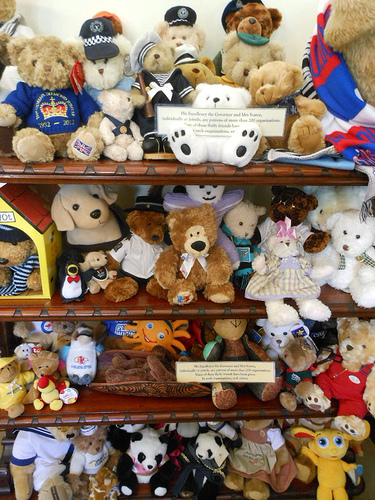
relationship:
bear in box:
[306, 213, 373, 272] [21, 206, 82, 300]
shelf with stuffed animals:
[0, 157, 372, 187] [3, 4, 371, 166]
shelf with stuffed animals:
[3, 292, 374, 320] [1, 185, 373, 302]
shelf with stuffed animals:
[0, 379, 369, 426] [1, 322, 374, 402]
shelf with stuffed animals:
[1, 473, 374, 499] [1, 419, 372, 496]